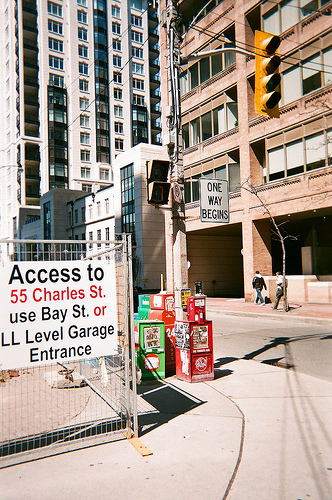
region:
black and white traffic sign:
[196, 176, 248, 234]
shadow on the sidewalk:
[150, 385, 197, 423]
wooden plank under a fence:
[133, 432, 153, 458]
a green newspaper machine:
[137, 322, 168, 398]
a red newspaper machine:
[175, 294, 219, 385]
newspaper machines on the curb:
[135, 291, 174, 315]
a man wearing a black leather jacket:
[252, 269, 268, 305]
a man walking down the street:
[271, 266, 289, 321]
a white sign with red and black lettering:
[2, 251, 122, 371]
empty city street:
[225, 313, 276, 354]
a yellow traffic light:
[246, 24, 281, 121]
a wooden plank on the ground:
[129, 434, 162, 457]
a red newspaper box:
[183, 300, 211, 378]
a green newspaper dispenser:
[135, 318, 166, 378]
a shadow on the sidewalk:
[143, 381, 199, 430]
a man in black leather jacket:
[250, 261, 265, 310]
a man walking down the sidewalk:
[273, 273, 289, 310]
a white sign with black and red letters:
[6, 258, 121, 371]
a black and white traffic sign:
[195, 178, 236, 224]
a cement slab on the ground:
[45, 364, 87, 387]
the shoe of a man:
[260, 301, 266, 306]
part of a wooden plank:
[118, 418, 158, 461]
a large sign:
[0, 260, 121, 373]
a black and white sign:
[197, 175, 233, 222]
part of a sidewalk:
[3, 363, 330, 498]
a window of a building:
[266, 146, 284, 179]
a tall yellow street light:
[248, 27, 288, 119]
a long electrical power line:
[192, 3, 330, 59]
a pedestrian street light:
[146, 156, 176, 208]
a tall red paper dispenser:
[174, 295, 217, 382]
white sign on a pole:
[184, 171, 245, 232]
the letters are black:
[181, 177, 243, 242]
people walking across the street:
[233, 257, 286, 321]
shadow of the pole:
[213, 318, 320, 373]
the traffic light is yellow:
[230, 16, 298, 135]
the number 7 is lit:
[140, 178, 181, 213]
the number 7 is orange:
[147, 178, 168, 212]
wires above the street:
[101, 4, 327, 106]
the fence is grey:
[11, 203, 152, 441]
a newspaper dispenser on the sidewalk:
[157, 272, 230, 391]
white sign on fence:
[3, 261, 121, 364]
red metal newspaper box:
[176, 297, 214, 378]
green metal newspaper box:
[140, 319, 166, 375]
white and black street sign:
[201, 179, 228, 222]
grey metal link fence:
[2, 239, 138, 468]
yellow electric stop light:
[253, 30, 281, 118]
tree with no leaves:
[241, 180, 293, 310]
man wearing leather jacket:
[252, 270, 267, 305]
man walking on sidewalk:
[274, 272, 289, 309]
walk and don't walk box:
[146, 159, 171, 206]